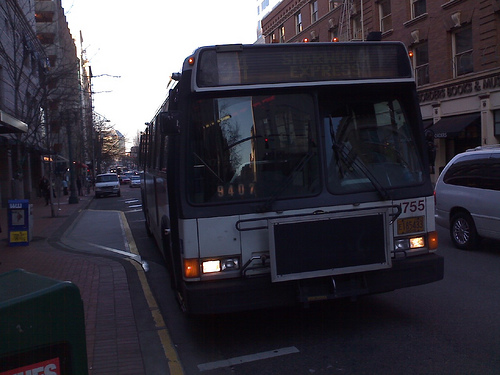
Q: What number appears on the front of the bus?
A: 755.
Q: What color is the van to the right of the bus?
A: White.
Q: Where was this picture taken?
A: A city street.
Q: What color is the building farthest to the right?
A: Brown.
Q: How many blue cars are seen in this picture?
A: Zero.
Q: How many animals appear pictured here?
A: Zero.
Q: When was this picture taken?
A: Sunset.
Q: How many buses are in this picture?
A: One.